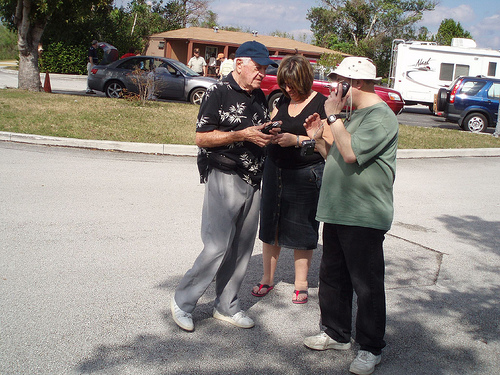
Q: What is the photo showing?
A: It is showing a pavement.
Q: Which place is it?
A: It is a pavement.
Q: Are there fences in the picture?
A: No, there are no fences.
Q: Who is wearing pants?
A: The man is wearing pants.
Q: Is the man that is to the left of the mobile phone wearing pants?
A: Yes, the man is wearing pants.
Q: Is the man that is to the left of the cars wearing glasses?
A: No, the man is wearing pants.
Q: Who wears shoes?
A: The man wears shoes.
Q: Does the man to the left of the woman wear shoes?
A: Yes, the man wears shoes.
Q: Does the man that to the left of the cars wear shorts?
A: No, the man wears shoes.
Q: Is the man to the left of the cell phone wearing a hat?
A: Yes, the man is wearing a hat.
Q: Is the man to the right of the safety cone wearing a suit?
A: No, the man is wearing a hat.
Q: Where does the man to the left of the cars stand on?
A: The man stands on the pavement.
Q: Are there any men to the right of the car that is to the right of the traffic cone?
A: Yes, there is a man to the right of the car.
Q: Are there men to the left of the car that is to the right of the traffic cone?
A: No, the man is to the right of the car.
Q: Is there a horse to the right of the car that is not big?
A: No, there is a man to the right of the car.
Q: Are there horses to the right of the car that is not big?
A: No, there is a man to the right of the car.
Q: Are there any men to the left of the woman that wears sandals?
A: Yes, there is a man to the left of the woman.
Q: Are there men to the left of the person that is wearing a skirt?
A: Yes, there is a man to the left of the woman.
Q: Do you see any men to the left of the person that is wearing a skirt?
A: Yes, there is a man to the left of the woman.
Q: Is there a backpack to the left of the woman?
A: No, there is a man to the left of the woman.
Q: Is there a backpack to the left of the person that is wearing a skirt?
A: No, there is a man to the left of the woman.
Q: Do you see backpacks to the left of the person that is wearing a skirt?
A: No, there is a man to the left of the woman.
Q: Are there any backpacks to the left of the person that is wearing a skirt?
A: No, there is a man to the left of the woman.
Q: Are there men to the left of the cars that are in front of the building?
A: Yes, there is a man to the left of the cars.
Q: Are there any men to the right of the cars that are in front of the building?
A: No, the man is to the left of the cars.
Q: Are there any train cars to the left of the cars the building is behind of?
A: No, there is a man to the left of the cars.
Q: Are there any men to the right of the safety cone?
A: Yes, there is a man to the right of the safety cone.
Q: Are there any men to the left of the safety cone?
A: No, the man is to the right of the safety cone.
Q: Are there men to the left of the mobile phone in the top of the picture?
A: Yes, there is a man to the left of the cell phone.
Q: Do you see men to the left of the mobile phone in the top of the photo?
A: Yes, there is a man to the left of the cell phone.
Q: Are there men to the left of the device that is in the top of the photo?
A: Yes, there is a man to the left of the cell phone.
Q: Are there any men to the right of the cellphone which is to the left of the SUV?
A: No, the man is to the left of the cellphone.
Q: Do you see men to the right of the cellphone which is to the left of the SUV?
A: No, the man is to the left of the cellphone.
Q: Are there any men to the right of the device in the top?
A: No, the man is to the left of the cellphone.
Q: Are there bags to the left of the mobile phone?
A: No, there is a man to the left of the mobile phone.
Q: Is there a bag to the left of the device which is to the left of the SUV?
A: No, there is a man to the left of the mobile phone.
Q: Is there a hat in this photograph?
A: Yes, there is a hat.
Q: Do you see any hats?
A: Yes, there is a hat.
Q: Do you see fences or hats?
A: Yes, there is a hat.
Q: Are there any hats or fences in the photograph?
A: Yes, there is a hat.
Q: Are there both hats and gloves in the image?
A: No, there is a hat but no gloves.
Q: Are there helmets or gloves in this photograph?
A: No, there are no helmets or gloves.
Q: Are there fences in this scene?
A: No, there are no fences.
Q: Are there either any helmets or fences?
A: No, there are no helmets or fences.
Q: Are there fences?
A: No, there are no fences.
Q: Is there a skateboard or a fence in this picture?
A: No, there are no fences or skateboards.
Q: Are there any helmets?
A: No, there are no helmets.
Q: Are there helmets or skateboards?
A: No, there are no helmets or skateboards.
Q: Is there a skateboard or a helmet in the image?
A: No, there are no helmets or skateboards.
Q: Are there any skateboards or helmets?
A: No, there are no helmets or skateboards.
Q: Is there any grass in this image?
A: Yes, there is grass.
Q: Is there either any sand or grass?
A: Yes, there is grass.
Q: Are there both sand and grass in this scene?
A: No, there is grass but no sand.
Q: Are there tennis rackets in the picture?
A: No, there are no tennis rackets.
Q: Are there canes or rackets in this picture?
A: No, there are no rackets or canes.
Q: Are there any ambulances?
A: No, there are no ambulances.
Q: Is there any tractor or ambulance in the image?
A: No, there are no ambulances or tractors.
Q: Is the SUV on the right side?
A: Yes, the SUV is on the right of the image.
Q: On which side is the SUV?
A: The SUV is on the right of the image.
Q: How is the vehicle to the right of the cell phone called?
A: The vehicle is a SUV.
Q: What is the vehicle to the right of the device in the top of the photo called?
A: The vehicle is a SUV.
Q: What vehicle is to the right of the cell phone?
A: The vehicle is a SUV.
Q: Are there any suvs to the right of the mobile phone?
A: Yes, there is a SUV to the right of the mobile phone.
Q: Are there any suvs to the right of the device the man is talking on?
A: Yes, there is a SUV to the right of the mobile phone.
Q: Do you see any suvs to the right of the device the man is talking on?
A: Yes, there is a SUV to the right of the mobile phone.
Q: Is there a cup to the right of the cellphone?
A: No, there is a SUV to the right of the cellphone.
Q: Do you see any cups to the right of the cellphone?
A: No, there is a SUV to the right of the cellphone.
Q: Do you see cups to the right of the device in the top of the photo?
A: No, there is a SUV to the right of the cellphone.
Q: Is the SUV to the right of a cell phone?
A: Yes, the SUV is to the right of a cell phone.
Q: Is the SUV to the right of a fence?
A: No, the SUV is to the right of a cell phone.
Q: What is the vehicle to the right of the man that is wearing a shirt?
A: The vehicle is a SUV.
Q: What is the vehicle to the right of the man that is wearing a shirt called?
A: The vehicle is a SUV.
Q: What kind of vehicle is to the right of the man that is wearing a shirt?
A: The vehicle is a SUV.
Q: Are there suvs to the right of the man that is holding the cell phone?
A: Yes, there is a SUV to the right of the man.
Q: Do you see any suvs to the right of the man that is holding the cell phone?
A: Yes, there is a SUV to the right of the man.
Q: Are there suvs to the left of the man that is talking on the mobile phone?
A: No, the SUV is to the right of the man.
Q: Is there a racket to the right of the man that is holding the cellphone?
A: No, there is a SUV to the right of the man.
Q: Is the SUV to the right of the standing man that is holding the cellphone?
A: Yes, the SUV is to the right of the man.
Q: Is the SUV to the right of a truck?
A: No, the SUV is to the right of the man.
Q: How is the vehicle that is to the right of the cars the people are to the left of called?
A: The vehicle is a SUV.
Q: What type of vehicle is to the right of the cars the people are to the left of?
A: The vehicle is a SUV.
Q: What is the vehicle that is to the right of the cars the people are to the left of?
A: The vehicle is a SUV.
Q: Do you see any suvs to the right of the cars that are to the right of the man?
A: Yes, there is a SUV to the right of the cars.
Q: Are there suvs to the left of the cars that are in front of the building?
A: No, the SUV is to the right of the cars.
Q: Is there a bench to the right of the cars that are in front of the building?
A: No, there is a SUV to the right of the cars.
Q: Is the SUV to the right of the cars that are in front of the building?
A: Yes, the SUV is to the right of the cars.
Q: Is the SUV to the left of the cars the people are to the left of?
A: No, the SUV is to the right of the cars.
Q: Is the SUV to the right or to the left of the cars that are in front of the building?
A: The SUV is to the right of the cars.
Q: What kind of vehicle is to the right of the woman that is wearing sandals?
A: The vehicle is a SUV.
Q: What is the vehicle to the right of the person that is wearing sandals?
A: The vehicle is a SUV.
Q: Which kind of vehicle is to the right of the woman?
A: The vehicle is a SUV.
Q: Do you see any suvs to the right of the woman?
A: Yes, there is a SUV to the right of the woman.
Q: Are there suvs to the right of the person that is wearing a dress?
A: Yes, there is a SUV to the right of the woman.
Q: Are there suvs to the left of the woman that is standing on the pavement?
A: No, the SUV is to the right of the woman.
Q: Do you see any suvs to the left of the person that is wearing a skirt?
A: No, the SUV is to the right of the woman.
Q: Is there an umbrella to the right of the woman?
A: No, there is a SUV to the right of the woman.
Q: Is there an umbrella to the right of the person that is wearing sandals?
A: No, there is a SUV to the right of the woman.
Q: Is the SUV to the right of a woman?
A: Yes, the SUV is to the right of a woman.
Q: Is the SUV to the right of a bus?
A: No, the SUV is to the right of a woman.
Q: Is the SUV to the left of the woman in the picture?
A: No, the SUV is to the right of the woman.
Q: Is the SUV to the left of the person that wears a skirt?
A: No, the SUV is to the right of the woman.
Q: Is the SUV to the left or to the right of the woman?
A: The SUV is to the right of the woman.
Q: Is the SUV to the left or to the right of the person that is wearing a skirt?
A: The SUV is to the right of the woman.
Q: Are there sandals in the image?
A: Yes, there are sandals.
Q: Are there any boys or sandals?
A: Yes, there are sandals.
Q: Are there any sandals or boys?
A: Yes, there are sandals.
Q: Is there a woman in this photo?
A: Yes, there is a woman.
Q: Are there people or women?
A: Yes, there is a woman.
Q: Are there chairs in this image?
A: No, there are no chairs.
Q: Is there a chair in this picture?
A: No, there are no chairs.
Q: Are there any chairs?
A: No, there are no chairs.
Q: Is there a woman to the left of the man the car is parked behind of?
A: Yes, there is a woman to the left of the man.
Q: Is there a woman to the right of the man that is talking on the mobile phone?
A: No, the woman is to the left of the man.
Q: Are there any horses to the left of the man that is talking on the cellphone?
A: No, there is a woman to the left of the man.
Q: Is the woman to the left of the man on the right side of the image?
A: Yes, the woman is to the left of the man.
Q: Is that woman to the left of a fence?
A: No, the woman is to the left of the man.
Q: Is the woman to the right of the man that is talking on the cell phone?
A: No, the woman is to the left of the man.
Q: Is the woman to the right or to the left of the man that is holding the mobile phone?
A: The woman is to the left of the man.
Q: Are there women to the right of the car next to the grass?
A: Yes, there is a woman to the right of the car.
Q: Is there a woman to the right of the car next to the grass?
A: Yes, there is a woman to the right of the car.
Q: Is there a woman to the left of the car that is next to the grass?
A: No, the woman is to the right of the car.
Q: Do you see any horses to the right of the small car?
A: No, there is a woman to the right of the car.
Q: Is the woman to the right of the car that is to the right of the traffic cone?
A: Yes, the woman is to the right of the car.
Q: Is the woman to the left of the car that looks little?
A: No, the woman is to the right of the car.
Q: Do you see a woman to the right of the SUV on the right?
A: No, the woman is to the left of the SUV.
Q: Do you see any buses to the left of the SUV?
A: No, there is a woman to the left of the SUV.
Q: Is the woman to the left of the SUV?
A: Yes, the woman is to the left of the SUV.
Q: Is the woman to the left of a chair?
A: No, the woman is to the left of the SUV.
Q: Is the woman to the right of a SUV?
A: No, the woman is to the left of a SUV.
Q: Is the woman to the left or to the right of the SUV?
A: The woman is to the left of the SUV.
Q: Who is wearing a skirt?
A: The woman is wearing a skirt.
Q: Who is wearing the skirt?
A: The woman is wearing a skirt.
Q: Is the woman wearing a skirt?
A: Yes, the woman is wearing a skirt.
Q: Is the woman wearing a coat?
A: No, the woman is wearing a skirt.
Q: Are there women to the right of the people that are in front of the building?
A: Yes, there is a woman to the right of the people.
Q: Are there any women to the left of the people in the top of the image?
A: No, the woman is to the right of the people.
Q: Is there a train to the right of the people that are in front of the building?
A: No, there is a woman to the right of the people.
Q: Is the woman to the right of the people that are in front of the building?
A: Yes, the woman is to the right of the people.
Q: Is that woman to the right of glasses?
A: No, the woman is to the right of the people.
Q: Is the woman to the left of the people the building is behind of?
A: No, the woman is to the right of the people.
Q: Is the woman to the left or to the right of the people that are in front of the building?
A: The woman is to the right of the people.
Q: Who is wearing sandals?
A: The woman is wearing sandals.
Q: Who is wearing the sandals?
A: The woman is wearing sandals.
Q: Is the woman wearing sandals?
A: Yes, the woman is wearing sandals.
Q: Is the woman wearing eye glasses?
A: No, the woman is wearing sandals.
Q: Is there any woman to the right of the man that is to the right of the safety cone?
A: Yes, there is a woman to the right of the man.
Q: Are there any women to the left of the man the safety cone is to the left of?
A: No, the woman is to the right of the man.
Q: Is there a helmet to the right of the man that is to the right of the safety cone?
A: No, there is a woman to the right of the man.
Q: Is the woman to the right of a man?
A: Yes, the woman is to the right of a man.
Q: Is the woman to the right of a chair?
A: No, the woman is to the right of a man.